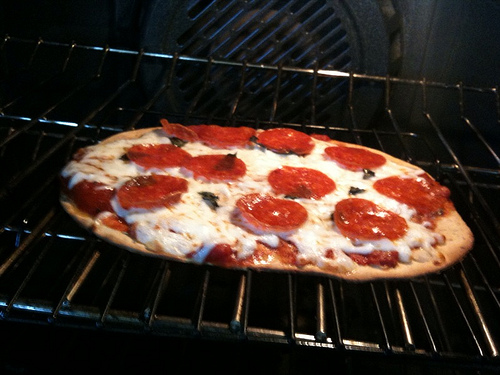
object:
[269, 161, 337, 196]
pepperoni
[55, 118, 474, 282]
pizza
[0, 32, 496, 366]
rack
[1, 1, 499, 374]
oven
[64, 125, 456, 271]
cheese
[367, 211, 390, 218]
glare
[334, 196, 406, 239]
pepperoni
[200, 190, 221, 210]
leaf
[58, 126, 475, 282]
crust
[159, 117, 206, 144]
pepperoni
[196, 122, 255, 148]
pepperoni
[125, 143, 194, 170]
pepperoni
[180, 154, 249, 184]
pepperoni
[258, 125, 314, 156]
pepperoni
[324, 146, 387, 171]
pepperoni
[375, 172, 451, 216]
pepperoni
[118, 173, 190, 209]
pepperoni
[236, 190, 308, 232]
pepperoni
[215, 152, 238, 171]
anchovies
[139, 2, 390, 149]
heater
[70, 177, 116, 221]
sauce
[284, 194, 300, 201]
leaf